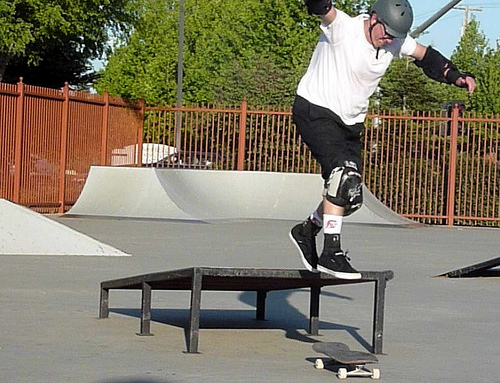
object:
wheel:
[314, 359, 323, 369]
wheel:
[338, 367, 348, 379]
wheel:
[371, 367, 380, 379]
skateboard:
[310, 341, 381, 380]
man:
[288, 1, 479, 280]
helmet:
[362, 0, 414, 38]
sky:
[411, 0, 499, 59]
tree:
[1, 1, 117, 87]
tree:
[94, 1, 307, 162]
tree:
[444, 7, 499, 116]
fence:
[0, 81, 497, 227]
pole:
[172, 1, 185, 149]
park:
[3, 0, 499, 382]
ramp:
[94, 263, 392, 357]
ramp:
[60, 165, 425, 223]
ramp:
[1, 190, 142, 259]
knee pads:
[323, 161, 364, 207]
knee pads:
[344, 183, 363, 215]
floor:
[4, 225, 499, 377]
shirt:
[294, 5, 417, 127]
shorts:
[276, 95, 378, 189]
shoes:
[314, 248, 363, 281]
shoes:
[288, 217, 322, 272]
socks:
[323, 214, 343, 235]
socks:
[308, 209, 322, 227]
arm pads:
[413, 45, 459, 85]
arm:
[402, 31, 457, 86]